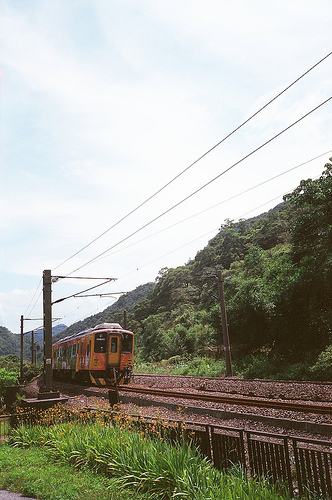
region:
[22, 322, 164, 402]
The train is on the track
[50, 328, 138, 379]
The train is yellow and red.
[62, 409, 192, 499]
The grass is green.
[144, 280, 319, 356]
Trees along side the tracks.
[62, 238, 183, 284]
Wires are above the train and tracks.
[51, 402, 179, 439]
The flowers are yellow.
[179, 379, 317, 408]
Gravel between the tracks.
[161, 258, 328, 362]
The trees are bushy and huge.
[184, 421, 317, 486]
An iron gate along side the tracks.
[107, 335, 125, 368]
A person is standing at the door of the train.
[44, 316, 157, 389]
yellow and red train on train tracks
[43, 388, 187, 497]
green plants next to train track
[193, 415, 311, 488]
brown fence next to train track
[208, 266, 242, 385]
brown telephone post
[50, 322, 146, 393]
yellow and red train with windows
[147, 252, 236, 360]
green trees on mountain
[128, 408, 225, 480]
green plants with orange flowers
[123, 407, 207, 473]
plants and a fence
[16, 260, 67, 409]
two telephone posts and wires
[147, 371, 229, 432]
train track on brown dirt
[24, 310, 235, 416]
a yellow train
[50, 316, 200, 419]
a train on tracks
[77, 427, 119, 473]
green grass on the side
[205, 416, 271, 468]
a fence separating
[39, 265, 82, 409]
a electric pole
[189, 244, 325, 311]
trees in the background by the train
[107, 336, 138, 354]
the window of the yellwo train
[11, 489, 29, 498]
cement on the side of the grass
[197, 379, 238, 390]
rocks near the train track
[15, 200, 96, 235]
some clouds in the sky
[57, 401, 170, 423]
The flowers are growing by the gate.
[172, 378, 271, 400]
Gravel between the tracks.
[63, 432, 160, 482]
The grass is green.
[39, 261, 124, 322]
Wires above the train and tracks.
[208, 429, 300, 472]
Iron gate beside the tracks.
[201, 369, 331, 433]
Tracks are brown and rusty.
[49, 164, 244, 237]
The sky is blue.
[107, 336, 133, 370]
The train door is in the front.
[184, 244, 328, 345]
The trees are green and bushy.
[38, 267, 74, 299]
an electric wire pole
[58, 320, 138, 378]
a yellow train car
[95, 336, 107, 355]
a window in a train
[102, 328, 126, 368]
a door on a train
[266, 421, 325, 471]
fence along the side of train tracks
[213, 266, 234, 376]
a pole along the side of train tracks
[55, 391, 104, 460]
orange flowers along the side of train tracks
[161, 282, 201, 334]
trees of a forest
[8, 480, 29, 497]
grass along the edge of a road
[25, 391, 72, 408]
cement base to a electrical pole